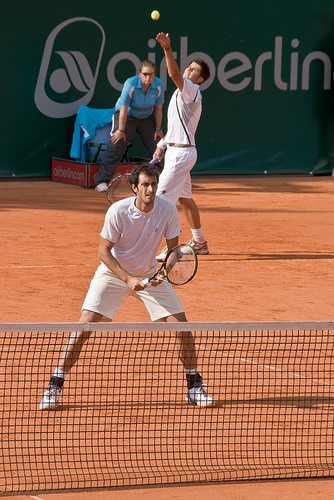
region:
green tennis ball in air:
[151, 10, 159, 19]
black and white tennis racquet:
[140, 241, 199, 289]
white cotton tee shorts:
[100, 197, 179, 279]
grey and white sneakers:
[37, 384, 219, 414]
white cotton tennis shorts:
[81, 261, 186, 319]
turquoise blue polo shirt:
[114, 77, 165, 119]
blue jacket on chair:
[70, 108, 115, 158]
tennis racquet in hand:
[105, 156, 159, 198]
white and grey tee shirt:
[165, 81, 202, 148]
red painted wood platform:
[49, 157, 145, 188]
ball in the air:
[136, 11, 205, 21]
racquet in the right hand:
[125, 256, 207, 285]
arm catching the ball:
[135, 2, 204, 105]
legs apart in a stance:
[46, 283, 211, 413]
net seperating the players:
[0, 321, 332, 481]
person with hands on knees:
[122, 63, 161, 142]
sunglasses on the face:
[137, 62, 162, 78]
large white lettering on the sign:
[208, 47, 332, 97]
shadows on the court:
[206, 169, 329, 271]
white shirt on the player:
[107, 215, 163, 264]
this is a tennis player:
[92, 163, 183, 285]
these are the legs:
[100, 294, 173, 317]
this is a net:
[243, 343, 284, 434]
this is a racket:
[141, 245, 198, 290]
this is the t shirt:
[122, 219, 155, 250]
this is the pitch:
[234, 215, 298, 294]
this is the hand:
[151, 33, 180, 73]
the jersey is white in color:
[170, 103, 194, 136]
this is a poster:
[19, 65, 76, 122]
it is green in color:
[8, 126, 57, 162]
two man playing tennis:
[5, 0, 327, 497]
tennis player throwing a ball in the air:
[133, 0, 223, 145]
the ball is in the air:
[142, 6, 169, 26]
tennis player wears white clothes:
[152, 31, 216, 254]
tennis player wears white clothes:
[29, 159, 221, 419]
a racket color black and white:
[128, 240, 204, 294]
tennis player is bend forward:
[16, 160, 231, 418]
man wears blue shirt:
[89, 55, 166, 176]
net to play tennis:
[3, 310, 332, 486]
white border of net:
[2, 314, 330, 489]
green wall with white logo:
[3, 1, 332, 175]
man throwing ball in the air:
[150, 9, 211, 253]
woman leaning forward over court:
[95, 60, 167, 192]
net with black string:
[0, 321, 333, 490]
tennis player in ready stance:
[39, 164, 214, 407]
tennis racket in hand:
[132, 242, 197, 289]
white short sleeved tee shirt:
[101, 195, 180, 270]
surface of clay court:
[0, 177, 331, 496]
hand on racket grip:
[150, 148, 165, 164]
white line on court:
[1, 255, 333, 269]